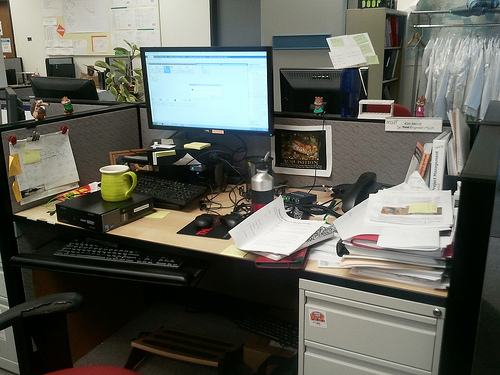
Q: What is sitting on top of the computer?
A: Green mug.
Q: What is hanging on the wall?
A: White coats.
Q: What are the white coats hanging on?
A: Hangers.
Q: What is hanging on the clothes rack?
A: White coats.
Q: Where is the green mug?
A: On a black box.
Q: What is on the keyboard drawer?
A: A keyboard.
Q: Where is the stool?
A: Under the desk.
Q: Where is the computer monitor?
A: On the desk.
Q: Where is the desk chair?
A: In front of the desk.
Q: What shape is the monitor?
A: Rectangular.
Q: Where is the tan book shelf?
A: Beside the coat rack.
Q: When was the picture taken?
A: Daytime.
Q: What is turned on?
A: Computer screen.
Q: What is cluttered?
A: Desk.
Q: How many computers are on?
A: One.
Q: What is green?
A: Mug.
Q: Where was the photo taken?
A: At an office.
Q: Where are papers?
A: On the desk.